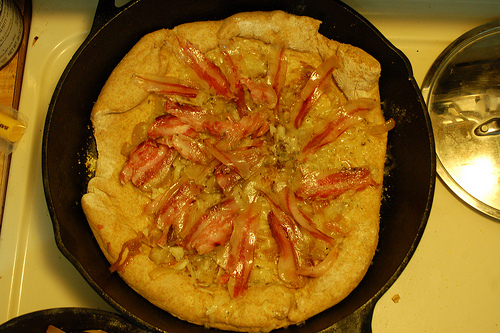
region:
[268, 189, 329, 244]
Red onions on a fajita.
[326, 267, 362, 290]
The crust is brown.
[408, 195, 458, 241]
The skillet is brown.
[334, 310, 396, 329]
The handle is black.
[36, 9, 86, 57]
The stove is white.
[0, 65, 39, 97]
Cabinet next to the stove is wooden.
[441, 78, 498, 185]
The skillet lid is silver.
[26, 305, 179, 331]
Another skillet in the corner.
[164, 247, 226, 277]
Cabbage under the onions.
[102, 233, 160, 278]
Burnt cabbage on the crust.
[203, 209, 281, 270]
bacon strips on a pizza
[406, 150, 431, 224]
a cast iron frying pan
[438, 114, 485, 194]
a metal pot lid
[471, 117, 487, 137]
a screw in the handle of the lid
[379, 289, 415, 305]
crumbs on the stove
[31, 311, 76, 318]
the edge of a black pan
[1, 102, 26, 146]
a plastic package next to the stove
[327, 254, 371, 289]
thick golden crust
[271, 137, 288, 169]
ground sausage sprinkled on the pizza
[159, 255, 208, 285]
melted cheese on the pizza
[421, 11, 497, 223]
A silver pot lid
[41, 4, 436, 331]
A black iron skillet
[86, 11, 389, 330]
A pizza in a skillet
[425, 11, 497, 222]
A pan on a stove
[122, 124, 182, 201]
A piece of bacon on a pizza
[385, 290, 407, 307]
A crust crumb on a stove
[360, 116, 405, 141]
A chopped piece of onion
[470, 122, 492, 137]
A round bolt on a lid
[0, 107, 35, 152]
A yellow end in plastic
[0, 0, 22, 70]
A jar on a counter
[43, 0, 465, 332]
cast iron skillet on stove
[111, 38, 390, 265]
caramelized onions atop bread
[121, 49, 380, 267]
bacon pieces atop bread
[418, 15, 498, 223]
stainless steel pot top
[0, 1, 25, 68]
can on counter near stove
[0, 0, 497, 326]
white stove near the counter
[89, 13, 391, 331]
hot water cornbread in skillet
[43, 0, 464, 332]
large black cast iron skillet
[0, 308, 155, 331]
small black cast iron skillet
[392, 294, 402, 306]
crumb of bread on stove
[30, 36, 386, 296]
one pizza is seen.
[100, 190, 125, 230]
bread is brown color.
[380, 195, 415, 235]
pan is black color.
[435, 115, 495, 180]
cover is silver color.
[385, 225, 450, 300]
pan is on stove.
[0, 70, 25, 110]
table is brown color.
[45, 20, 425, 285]
one pan is seen.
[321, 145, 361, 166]
cheese is white color.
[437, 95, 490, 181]
one lid is seen.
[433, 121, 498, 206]
light reflection is seen in lid.